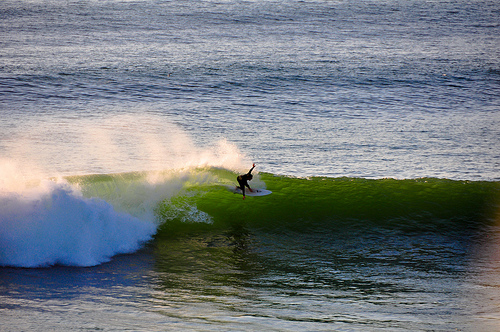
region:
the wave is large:
[20, 158, 157, 278]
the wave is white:
[6, 168, 151, 295]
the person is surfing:
[230, 169, 280, 213]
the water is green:
[286, 164, 394, 303]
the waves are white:
[72, 72, 208, 163]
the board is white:
[230, 173, 268, 205]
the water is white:
[33, 200, 124, 261]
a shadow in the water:
[174, 240, 261, 272]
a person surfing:
[230, 164, 262, 194]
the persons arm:
[248, 165, 258, 171]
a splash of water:
[83, 125, 148, 165]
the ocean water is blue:
[155, 50, 292, 93]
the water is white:
[37, 203, 95, 242]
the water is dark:
[83, 292, 154, 326]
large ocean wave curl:
[2, 164, 498, 268]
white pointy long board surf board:
[223, 183, 273, 197]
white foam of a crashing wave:
[0, 173, 192, 266]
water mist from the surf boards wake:
[2, 111, 266, 222]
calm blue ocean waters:
[0, 0, 499, 178]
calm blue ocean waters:
[0, 210, 497, 330]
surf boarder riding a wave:
[234, 163, 260, 201]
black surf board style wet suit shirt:
[239, 165, 255, 196]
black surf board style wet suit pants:
[236, 173, 254, 191]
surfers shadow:
[224, 220, 258, 249]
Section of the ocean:
[394, 270, 496, 327]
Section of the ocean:
[227, 238, 369, 329]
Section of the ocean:
[68, 190, 229, 329]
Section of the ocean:
[292, 114, 478, 232]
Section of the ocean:
[60, 36, 280, 128]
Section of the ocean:
[310, 28, 461, 124]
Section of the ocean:
[1, 118, 204, 330]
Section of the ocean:
[275, 60, 485, 169]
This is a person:
[224, 155, 280, 218]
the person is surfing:
[234, 164, 281, 217]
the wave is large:
[29, 189, 149, 268]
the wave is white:
[121, 166, 218, 254]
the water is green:
[182, 199, 347, 285]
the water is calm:
[265, 41, 409, 155]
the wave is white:
[24, 159, 153, 282]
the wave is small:
[93, 130, 237, 208]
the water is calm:
[76, 253, 216, 323]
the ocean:
[2, 4, 495, 323]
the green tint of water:
[65, 162, 498, 304]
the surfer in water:
[232, 158, 257, 205]